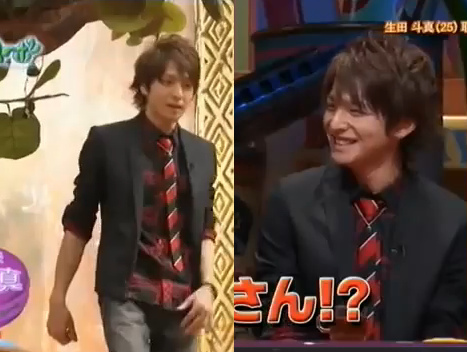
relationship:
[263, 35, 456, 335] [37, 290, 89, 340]
man has left hand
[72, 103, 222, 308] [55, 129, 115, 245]
coat has sleeves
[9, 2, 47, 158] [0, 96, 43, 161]
tree has leaf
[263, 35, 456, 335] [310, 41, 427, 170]
man has head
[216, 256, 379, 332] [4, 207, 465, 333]
writing in front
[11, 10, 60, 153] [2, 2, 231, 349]
design on wall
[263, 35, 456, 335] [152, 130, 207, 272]
man wearing tie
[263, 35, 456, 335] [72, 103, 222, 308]
man wearing suit jacket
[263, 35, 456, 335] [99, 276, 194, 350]
man wearing jeans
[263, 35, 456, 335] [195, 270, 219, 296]
man wearing watch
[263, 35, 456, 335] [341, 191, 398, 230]
man wearing necklace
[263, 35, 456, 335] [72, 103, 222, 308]
man wearing jacket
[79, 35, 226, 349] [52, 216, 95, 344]
man has arm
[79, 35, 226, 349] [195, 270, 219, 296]
he wearing watch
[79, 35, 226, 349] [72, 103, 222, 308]
man wearing jacket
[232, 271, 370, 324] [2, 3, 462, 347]
words on screen